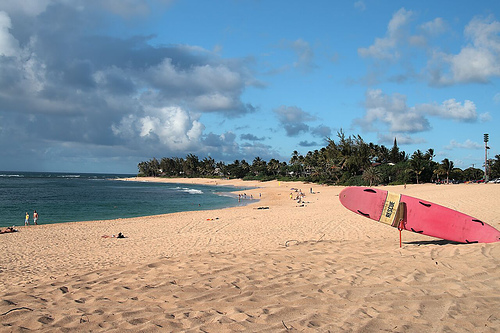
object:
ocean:
[0, 162, 265, 228]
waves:
[173, 184, 202, 198]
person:
[0, 224, 19, 233]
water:
[0, 172, 258, 228]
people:
[238, 192, 262, 203]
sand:
[1, 175, 500, 332]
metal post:
[485, 142, 488, 184]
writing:
[385, 200, 395, 219]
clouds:
[0, 1, 498, 168]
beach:
[0, 178, 499, 333]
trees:
[301, 128, 453, 185]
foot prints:
[0, 257, 500, 332]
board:
[337, 186, 500, 244]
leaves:
[135, 127, 500, 189]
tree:
[227, 158, 249, 178]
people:
[33, 210, 39, 225]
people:
[288, 187, 309, 207]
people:
[24, 211, 29, 226]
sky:
[0, 0, 499, 174]